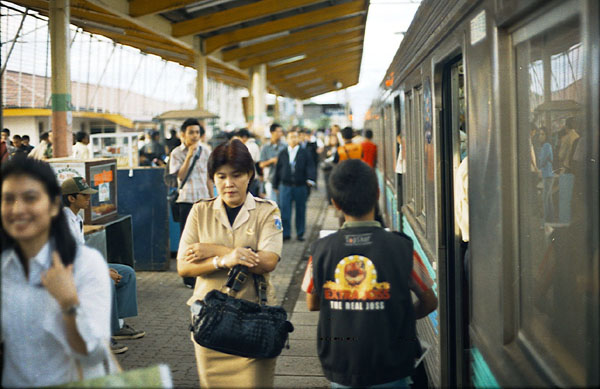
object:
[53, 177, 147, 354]
man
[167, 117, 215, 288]
man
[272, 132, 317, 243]
man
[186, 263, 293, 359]
purse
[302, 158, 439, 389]
person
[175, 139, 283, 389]
person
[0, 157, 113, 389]
person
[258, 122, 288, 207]
person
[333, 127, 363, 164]
person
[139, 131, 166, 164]
person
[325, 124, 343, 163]
person